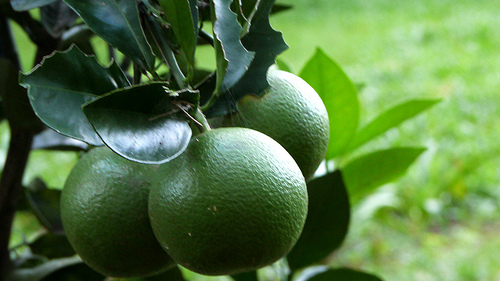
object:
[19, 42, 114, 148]
leaf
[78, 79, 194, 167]
leaf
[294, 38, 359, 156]
pizza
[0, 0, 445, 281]
lime tree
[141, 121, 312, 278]
lime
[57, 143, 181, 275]
orange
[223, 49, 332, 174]
orange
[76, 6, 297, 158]
orchids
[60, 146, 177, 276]
fruit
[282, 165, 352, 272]
leaf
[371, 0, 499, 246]
plants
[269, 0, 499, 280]
ground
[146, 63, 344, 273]
white plate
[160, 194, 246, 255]
imperfections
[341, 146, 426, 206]
leaf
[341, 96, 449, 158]
leaf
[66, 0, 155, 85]
leaf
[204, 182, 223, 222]
spot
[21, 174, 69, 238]
leaves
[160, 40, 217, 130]
branch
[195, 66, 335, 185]
fruits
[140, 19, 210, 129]
stem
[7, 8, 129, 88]
branch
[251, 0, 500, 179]
background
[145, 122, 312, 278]
fruit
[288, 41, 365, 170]
leaf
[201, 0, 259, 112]
leaf